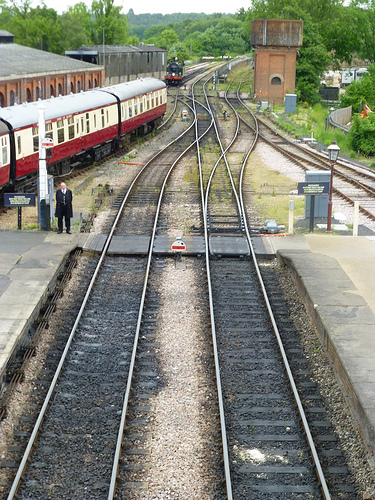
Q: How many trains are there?
A: One.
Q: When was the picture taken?
A: Daytime.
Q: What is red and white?
A: A train.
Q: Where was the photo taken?
A: At a train station.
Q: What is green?
A: Trees.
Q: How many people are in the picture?
A: One.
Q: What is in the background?
A: Trees.